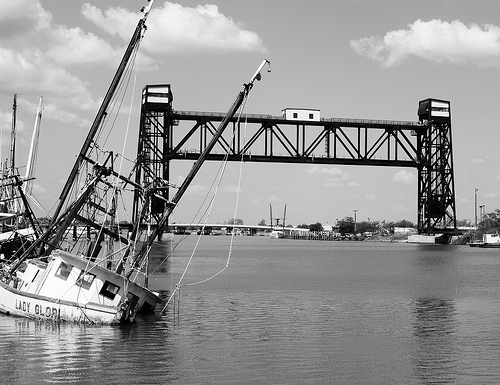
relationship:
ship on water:
[5, 51, 266, 326] [3, 220, 495, 373]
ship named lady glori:
[5, 51, 266, 326] [14, 299, 68, 323]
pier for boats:
[125, 220, 317, 239] [171, 230, 294, 237]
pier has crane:
[125, 220, 317, 239] [270, 202, 292, 241]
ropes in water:
[158, 95, 255, 318] [3, 220, 495, 373]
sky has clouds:
[11, 3, 493, 220] [7, 0, 498, 147]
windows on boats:
[49, 257, 163, 320] [5, 144, 152, 330]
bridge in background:
[128, 214, 319, 236] [21, 23, 488, 234]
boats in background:
[171, 230, 294, 237] [21, 23, 488, 234]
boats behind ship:
[171, 230, 294, 237] [5, 51, 266, 326]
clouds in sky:
[7, 0, 498, 147] [11, 3, 493, 220]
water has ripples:
[3, 220, 495, 373] [29, 321, 173, 376]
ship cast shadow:
[5, 51, 266, 326] [12, 322, 195, 378]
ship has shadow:
[5, 51, 266, 326] [12, 322, 195, 378]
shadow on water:
[12, 322, 195, 378] [3, 220, 495, 373]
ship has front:
[5, 51, 266, 326] [22, 255, 164, 317]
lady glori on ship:
[14, 299, 68, 323] [5, 51, 266, 326]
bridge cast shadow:
[136, 83, 460, 246] [412, 298, 457, 382]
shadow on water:
[412, 298, 457, 382] [3, 220, 495, 373]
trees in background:
[315, 215, 412, 229] [21, 23, 488, 234]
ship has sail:
[5, 51, 266, 326] [23, 98, 46, 206]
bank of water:
[375, 220, 499, 248] [3, 220, 495, 373]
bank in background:
[375, 220, 499, 248] [21, 23, 488, 234]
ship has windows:
[5, 51, 266, 326] [49, 257, 163, 320]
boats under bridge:
[171, 230, 294, 237] [128, 214, 319, 236]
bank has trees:
[375, 220, 499, 248] [315, 215, 412, 229]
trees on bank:
[315, 215, 412, 229] [375, 220, 499, 248]